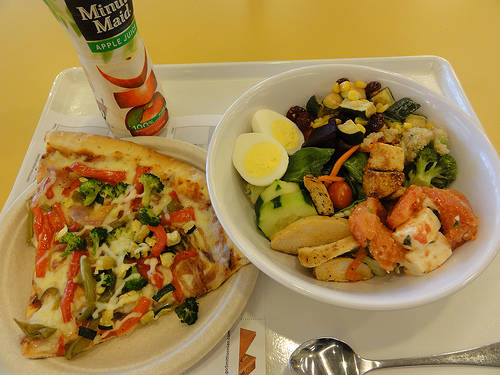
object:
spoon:
[288, 337, 498, 374]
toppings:
[75, 190, 149, 259]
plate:
[3, 130, 262, 373]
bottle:
[45, 0, 173, 143]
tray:
[0, 46, 498, 375]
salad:
[263, 106, 441, 262]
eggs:
[231, 133, 289, 186]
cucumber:
[256, 190, 318, 241]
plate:
[207, 63, 497, 315]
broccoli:
[61, 232, 85, 259]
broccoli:
[138, 173, 165, 206]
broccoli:
[123, 265, 149, 291]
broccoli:
[174, 296, 200, 325]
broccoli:
[80, 180, 102, 207]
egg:
[251, 108, 305, 157]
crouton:
[367, 141, 405, 172]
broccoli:
[88, 226, 109, 256]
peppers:
[148, 225, 167, 257]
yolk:
[244, 141, 282, 178]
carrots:
[331, 145, 360, 177]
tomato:
[327, 180, 353, 210]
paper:
[18, 109, 223, 185]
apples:
[97, 45, 148, 88]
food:
[16, 121, 253, 359]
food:
[228, 78, 488, 286]